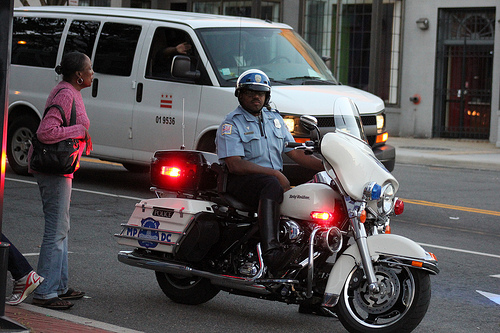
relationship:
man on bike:
[214, 62, 328, 247] [131, 125, 418, 331]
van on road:
[10, 2, 399, 195] [3, 126, 499, 331]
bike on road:
[131, 125, 418, 331] [3, 126, 499, 331]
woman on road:
[29, 34, 104, 307] [3, 126, 499, 331]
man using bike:
[214, 62, 328, 247] [131, 125, 418, 331]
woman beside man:
[29, 34, 104, 307] [214, 62, 328, 247]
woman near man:
[29, 34, 104, 307] [214, 62, 328, 247]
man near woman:
[214, 62, 328, 247] [29, 34, 104, 307]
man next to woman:
[214, 62, 328, 247] [29, 34, 104, 307]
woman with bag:
[29, 34, 104, 307] [34, 104, 80, 172]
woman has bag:
[29, 34, 104, 307] [34, 104, 80, 172]